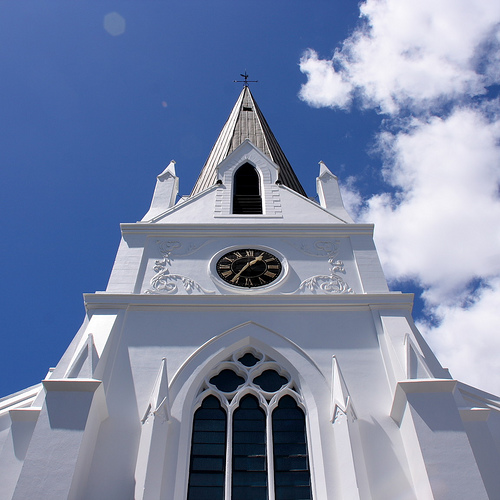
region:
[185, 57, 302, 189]
steeple on the building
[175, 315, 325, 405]
arch on top of the window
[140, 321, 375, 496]
large window on the building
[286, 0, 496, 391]
thick white clouds in the sky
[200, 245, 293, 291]
clock on the building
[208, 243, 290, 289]
gold and black clock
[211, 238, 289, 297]
roman numerals around the circumference of the clock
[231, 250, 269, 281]
two gold clock hands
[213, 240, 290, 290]
clock indicating it's about 1:35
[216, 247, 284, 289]
Black and gold clock.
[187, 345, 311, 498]
A shuttered church window.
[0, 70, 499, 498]
A white church cathedral.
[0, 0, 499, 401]
A blue sky with clouds.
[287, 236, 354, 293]
Some white building decorations.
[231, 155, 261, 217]
A small black window.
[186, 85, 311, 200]
A brown pointed roof.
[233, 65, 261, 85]
A metal wind vane.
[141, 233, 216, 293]
White scroll wall decorations.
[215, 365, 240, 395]
window of a church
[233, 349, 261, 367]
window of a church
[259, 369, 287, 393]
window of a church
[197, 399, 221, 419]
window of a church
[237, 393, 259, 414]
window of a church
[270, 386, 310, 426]
window of a church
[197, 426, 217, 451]
window of a church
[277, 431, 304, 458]
window of a church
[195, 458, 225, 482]
window of a church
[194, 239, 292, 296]
clock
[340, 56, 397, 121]
white clouds in blue sky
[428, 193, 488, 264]
white clouds in blue sky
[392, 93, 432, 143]
white clouds in blue sky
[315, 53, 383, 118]
white clouds in blue sky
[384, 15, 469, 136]
white clouds in blue sky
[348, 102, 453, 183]
white clouds in blue sky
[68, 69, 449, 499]
tall white building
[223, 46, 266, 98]
weather vane on top of roof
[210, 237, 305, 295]
time on clock is 1:35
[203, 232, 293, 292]
clock has roman numeral numbers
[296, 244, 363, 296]
floral design on wall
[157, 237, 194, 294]
floral design on wall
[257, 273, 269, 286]
roman numeral for the number five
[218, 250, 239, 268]
roman numeral for the number ten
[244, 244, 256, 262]
roman numeral for the number twelve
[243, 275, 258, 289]
roman numeral for the number six